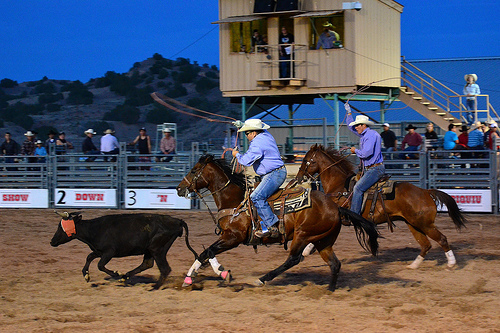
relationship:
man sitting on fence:
[95, 120, 121, 163] [9, 142, 482, 202]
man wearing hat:
[95, 120, 121, 163] [104, 126, 116, 133]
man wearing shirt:
[95, 120, 121, 163] [100, 133, 112, 152]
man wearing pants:
[95, 120, 121, 163] [102, 147, 129, 161]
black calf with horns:
[50, 210, 197, 298] [51, 207, 83, 219]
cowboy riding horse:
[232, 117, 287, 234] [173, 153, 375, 292]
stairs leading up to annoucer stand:
[385, 73, 472, 137] [209, 5, 426, 106]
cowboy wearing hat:
[345, 115, 383, 222] [345, 112, 375, 127]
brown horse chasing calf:
[187, 152, 359, 278] [46, 207, 209, 287]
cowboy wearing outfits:
[343, 103, 386, 223] [223, 96, 397, 241]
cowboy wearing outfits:
[231, 118, 288, 237] [223, 96, 397, 241]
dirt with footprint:
[1, 207, 498, 332] [440, 295, 474, 312]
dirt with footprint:
[1, 207, 498, 332] [384, 300, 430, 322]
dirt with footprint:
[1, 207, 498, 332] [349, 292, 388, 310]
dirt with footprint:
[1, 207, 498, 332] [297, 287, 349, 308]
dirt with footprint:
[1, 207, 498, 332] [465, 246, 498, 271]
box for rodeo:
[214, 0, 410, 103] [24, 102, 483, 312]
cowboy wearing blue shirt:
[231, 118, 288, 237] [245, 137, 294, 174]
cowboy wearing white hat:
[231, 118, 288, 237] [234, 112, 267, 136]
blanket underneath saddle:
[280, 197, 312, 213] [246, 168, 314, 217]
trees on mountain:
[129, 40, 203, 105] [47, 66, 239, 154]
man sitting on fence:
[100, 129, 122, 162] [0, 136, 499, 213]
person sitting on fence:
[82, 128, 102, 169] [0, 136, 499, 213]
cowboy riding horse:
[231, 118, 288, 237] [177, 150, 382, 298]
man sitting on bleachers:
[398, 118, 427, 162] [349, 124, 494, 174]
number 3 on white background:
[124, 188, 137, 206] [140, 189, 198, 212]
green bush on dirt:
[96, 101, 145, 131] [178, 280, 331, 331]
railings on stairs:
[406, 67, 448, 104] [400, 90, 447, 123]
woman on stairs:
[462, 69, 476, 120] [400, 90, 447, 123]